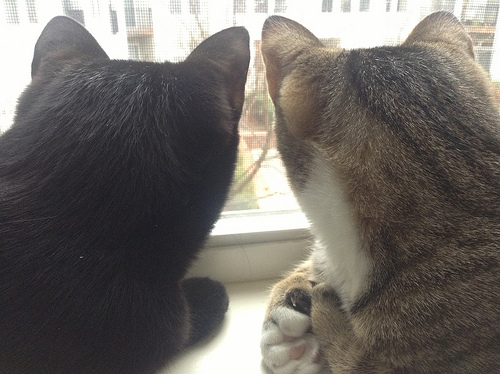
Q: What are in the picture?
A: Cats.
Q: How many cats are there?
A: Two.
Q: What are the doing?
A: Looking out the windows.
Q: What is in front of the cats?
A: Window.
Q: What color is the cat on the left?
A: Black.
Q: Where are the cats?
A: On the window sill.